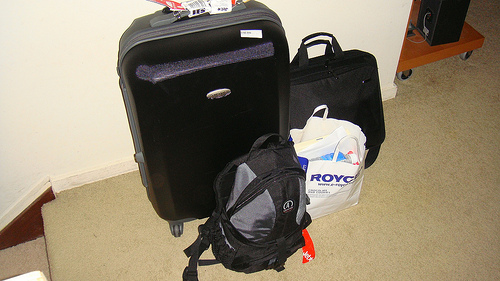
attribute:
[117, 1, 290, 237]
suitcase — grey, hard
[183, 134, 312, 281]
backpack — black, grey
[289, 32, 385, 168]
bag — black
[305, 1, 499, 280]
carpet — white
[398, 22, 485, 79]
cart — wooden, squared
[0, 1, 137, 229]
wall — white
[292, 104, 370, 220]
bag — plastic, white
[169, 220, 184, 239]
wheel — black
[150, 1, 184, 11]
tag — red